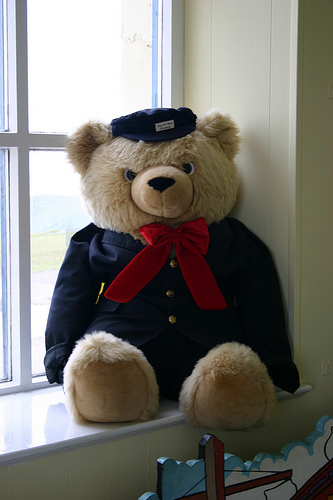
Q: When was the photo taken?
A: Daytime.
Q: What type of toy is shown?
A: Bear.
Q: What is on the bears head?
A: Hat.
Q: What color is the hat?
A: Blue.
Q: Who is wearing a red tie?
A: Teddy bear.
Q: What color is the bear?
A: Tan.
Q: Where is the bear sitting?
A: Windowsill.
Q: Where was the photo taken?
A: In a building with childrens decorations.